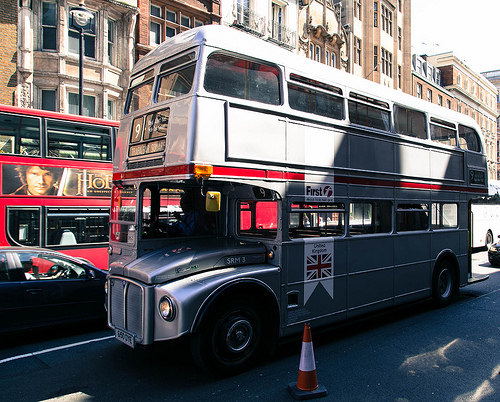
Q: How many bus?
A: 2.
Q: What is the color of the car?
A: Black.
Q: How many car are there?
A: 1.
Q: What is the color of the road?
A: Grey.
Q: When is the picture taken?
A: Daytime.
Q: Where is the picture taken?
A: In traffic.